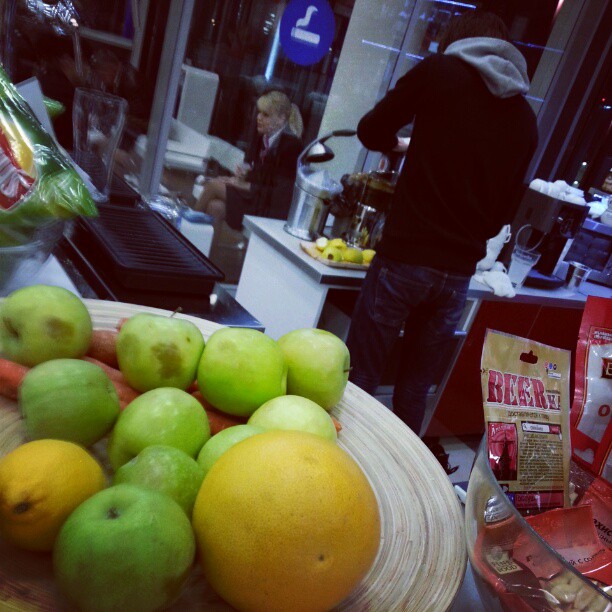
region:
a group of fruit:
[19, 261, 423, 609]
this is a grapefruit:
[187, 420, 407, 608]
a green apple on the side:
[280, 317, 365, 412]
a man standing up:
[333, 0, 555, 460]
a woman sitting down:
[173, 87, 309, 250]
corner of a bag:
[0, 76, 120, 292]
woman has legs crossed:
[173, 85, 327, 279]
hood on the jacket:
[443, 15, 549, 126]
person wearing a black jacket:
[340, 37, 566, 303]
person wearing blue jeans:
[346, 232, 505, 454]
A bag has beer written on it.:
[482, 328, 576, 525]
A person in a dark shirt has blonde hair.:
[246, 93, 303, 210]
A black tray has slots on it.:
[78, 193, 221, 306]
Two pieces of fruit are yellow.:
[5, 436, 379, 610]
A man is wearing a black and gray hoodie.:
[361, 29, 539, 273]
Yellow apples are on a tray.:
[299, 232, 377, 270]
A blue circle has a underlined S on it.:
[275, 0, 335, 67]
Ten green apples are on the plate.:
[1, 289, 354, 607]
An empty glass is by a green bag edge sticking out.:
[75, 85, 130, 205]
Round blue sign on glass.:
[276, 4, 336, 65]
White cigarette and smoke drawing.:
[285, 5, 322, 49]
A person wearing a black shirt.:
[357, 25, 538, 411]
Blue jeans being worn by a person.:
[355, 261, 472, 424]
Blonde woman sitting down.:
[201, 86, 303, 223]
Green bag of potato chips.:
[0, 80, 100, 242]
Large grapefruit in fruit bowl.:
[194, 416, 391, 607]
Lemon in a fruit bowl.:
[0, 437, 119, 562]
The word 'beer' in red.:
[487, 365, 546, 413]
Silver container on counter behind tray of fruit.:
[281, 153, 339, 249]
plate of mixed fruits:
[0, 280, 382, 610]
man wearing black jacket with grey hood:
[349, 14, 543, 442]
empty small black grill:
[62, 189, 229, 309]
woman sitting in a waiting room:
[194, 85, 300, 233]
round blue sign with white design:
[272, 2, 340, 68]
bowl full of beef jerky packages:
[451, 295, 610, 609]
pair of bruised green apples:
[3, 280, 207, 384]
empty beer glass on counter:
[65, 79, 130, 198]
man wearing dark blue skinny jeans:
[340, 10, 546, 435]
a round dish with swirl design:
[0, 285, 469, 607]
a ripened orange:
[193, 430, 381, 610]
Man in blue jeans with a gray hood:
[354, 11, 540, 463]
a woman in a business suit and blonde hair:
[200, 86, 309, 240]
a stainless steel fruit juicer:
[284, 127, 359, 239]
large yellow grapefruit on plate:
[191, 427, 383, 610]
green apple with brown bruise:
[0, 283, 93, 370]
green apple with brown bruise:
[116, 313, 204, 390]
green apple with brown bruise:
[50, 484, 196, 606]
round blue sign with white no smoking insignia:
[279, 3, 336, 65]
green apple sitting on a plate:
[197, 324, 290, 418]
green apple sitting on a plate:
[278, 322, 351, 408]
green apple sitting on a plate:
[15, 358, 120, 448]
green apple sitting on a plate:
[109, 387, 207, 468]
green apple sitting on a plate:
[112, 446, 202, 515]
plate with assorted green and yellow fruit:
[1, 281, 467, 610]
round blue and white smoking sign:
[278, 0, 338, 68]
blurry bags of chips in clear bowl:
[0, 66, 103, 295]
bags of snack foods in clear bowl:
[460, 293, 610, 608]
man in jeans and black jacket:
[336, 12, 540, 438]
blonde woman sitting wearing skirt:
[192, 87, 303, 257]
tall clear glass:
[68, 83, 127, 201]